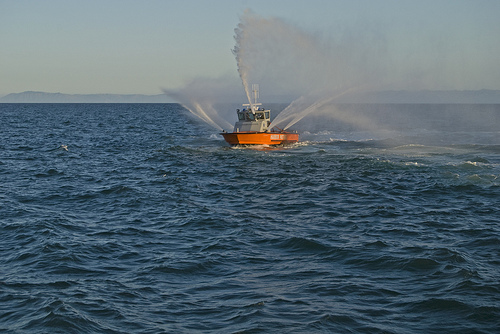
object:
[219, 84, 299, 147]
boat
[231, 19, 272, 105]
water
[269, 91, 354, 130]
water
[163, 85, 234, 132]
water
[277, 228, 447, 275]
waves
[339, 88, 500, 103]
mountains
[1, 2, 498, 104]
background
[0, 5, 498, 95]
sky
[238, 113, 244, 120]
window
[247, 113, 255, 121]
window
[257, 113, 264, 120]
window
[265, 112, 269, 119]
window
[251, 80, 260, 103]
antenna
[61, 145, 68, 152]
bird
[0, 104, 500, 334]
ocean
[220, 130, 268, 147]
hull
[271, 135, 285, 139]
words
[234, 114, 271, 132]
cabin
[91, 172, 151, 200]
waves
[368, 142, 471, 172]
waves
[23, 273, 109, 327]
waves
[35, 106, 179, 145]
waves